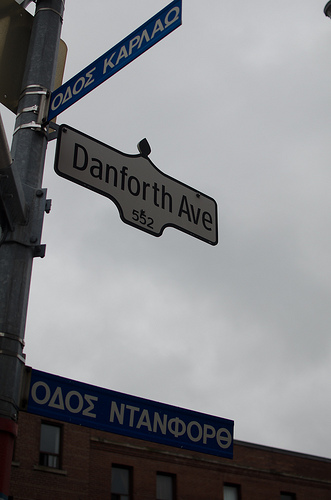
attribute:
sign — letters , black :
[34, 97, 264, 257]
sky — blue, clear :
[152, 58, 328, 158]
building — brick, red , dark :
[1, 412, 330, 499]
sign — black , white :
[49, 116, 251, 250]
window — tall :
[110, 462, 136, 496]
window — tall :
[40, 417, 63, 469]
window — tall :
[157, 472, 177, 497]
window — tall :
[223, 483, 244, 497]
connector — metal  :
[11, 119, 46, 135]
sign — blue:
[23, 358, 233, 458]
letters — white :
[50, 4, 180, 109]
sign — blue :
[50, 0, 183, 117]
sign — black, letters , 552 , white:
[57, 122, 222, 246]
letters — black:
[71, 140, 213, 230]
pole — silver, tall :
[4, 25, 72, 256]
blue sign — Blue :
[47, 0, 196, 124]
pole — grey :
[0, 0, 64, 496]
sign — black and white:
[66, 138, 218, 236]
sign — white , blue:
[15, 351, 250, 457]